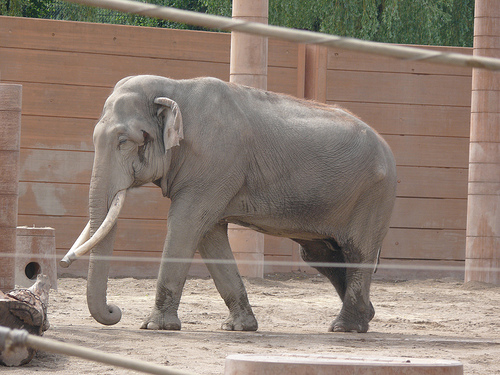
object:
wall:
[0, 27, 483, 277]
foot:
[219, 310, 257, 332]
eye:
[119, 138, 127, 144]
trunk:
[86, 161, 128, 326]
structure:
[229, 0, 499, 282]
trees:
[4, 0, 479, 56]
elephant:
[58, 74, 398, 335]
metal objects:
[204, 14, 499, 71]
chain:
[9, 289, 46, 325]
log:
[0, 272, 52, 368]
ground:
[413, 304, 436, 336]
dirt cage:
[0, 277, 499, 375]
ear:
[153, 96, 184, 155]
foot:
[139, 309, 180, 330]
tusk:
[58, 219, 90, 268]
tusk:
[68, 191, 127, 263]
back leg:
[327, 236, 384, 332]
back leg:
[298, 242, 374, 324]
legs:
[154, 203, 223, 315]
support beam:
[228, 1, 272, 276]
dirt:
[50, 276, 482, 365]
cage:
[0, 1, 499, 374]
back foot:
[327, 306, 368, 333]